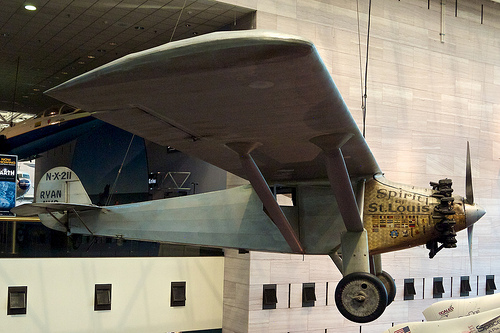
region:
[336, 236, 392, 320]
two wheels are visible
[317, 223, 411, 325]
two wheels are visible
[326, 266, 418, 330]
two wheels are visible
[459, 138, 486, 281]
propeller of air plane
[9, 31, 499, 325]
air plane model hanging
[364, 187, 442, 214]
spirit of St Louis decal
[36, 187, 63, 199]
Ryan decal on the tail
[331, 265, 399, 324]
tires on the air plane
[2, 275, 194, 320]
little windows on building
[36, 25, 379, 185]
right wing of air plane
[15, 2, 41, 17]
ceiling light in building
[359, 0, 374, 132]
front cable holding plane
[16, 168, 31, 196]
nose of airplane in background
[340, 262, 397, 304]
two wheels are visible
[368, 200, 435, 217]
St. Louis written on a plane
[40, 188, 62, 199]
Ryan written on a plane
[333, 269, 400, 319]
Two wheels on a plane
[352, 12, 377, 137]
Cable attached to a plane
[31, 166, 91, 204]
Round tail fin on a plane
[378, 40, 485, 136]
White tiles on the wall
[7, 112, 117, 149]
Blue underbelly of a plane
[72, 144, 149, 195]
Blue paint on a wall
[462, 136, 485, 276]
Propeller on the front on a plane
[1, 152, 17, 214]
Sign in a museum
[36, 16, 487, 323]
plane suspended from cables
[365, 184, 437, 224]
name of plane on nose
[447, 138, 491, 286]
propeller on front of plane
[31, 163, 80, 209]
letters and numbers on tail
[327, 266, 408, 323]
two wheels under plane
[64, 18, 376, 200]
wing on side of plane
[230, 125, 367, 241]
two braces under wing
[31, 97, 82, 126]
glass dome of cockpit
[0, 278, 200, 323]
three black squares on wall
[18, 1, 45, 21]
recessed light in ceiling